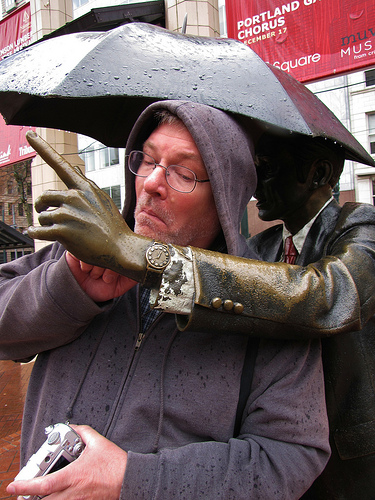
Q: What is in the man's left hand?
A: A camera.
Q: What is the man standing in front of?
A: A statue.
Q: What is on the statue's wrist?
A: A watch.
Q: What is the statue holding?
A: An umbrella.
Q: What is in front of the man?
A: Statue.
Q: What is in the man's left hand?
A: Camera.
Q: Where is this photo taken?
A: Portland.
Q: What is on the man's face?
A: Glasses.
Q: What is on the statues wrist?
A: Watch.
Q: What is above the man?
A: Umbrella.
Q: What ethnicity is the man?
A: Caucasian.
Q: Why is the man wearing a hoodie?
A: It is raining.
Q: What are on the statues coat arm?
A: Buttons.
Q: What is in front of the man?
A: The statue's arm.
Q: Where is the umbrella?
A: Over the statue's head.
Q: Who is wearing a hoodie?
A: The man in the glasses.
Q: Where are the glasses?
A: On the man's face.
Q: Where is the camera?
A: In the man's hand.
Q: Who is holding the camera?
A: The man in the gray hoodie.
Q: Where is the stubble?
A: On the real man's face.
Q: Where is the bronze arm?
A: In front of the male human.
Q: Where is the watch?
A: On the statue's wrist.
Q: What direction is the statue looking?
A: Left.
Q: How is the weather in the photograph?
A: Rainy.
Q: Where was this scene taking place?
A: In a big city.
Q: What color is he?
A: White.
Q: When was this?
A: Daytime.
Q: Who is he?
A: A man.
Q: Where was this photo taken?
A: Next to the statue.